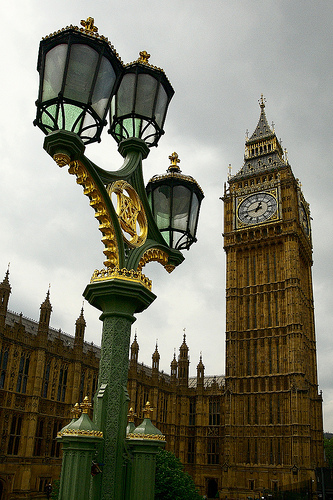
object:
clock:
[234, 189, 279, 229]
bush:
[153, 444, 200, 500]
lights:
[141, 151, 206, 257]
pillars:
[125, 432, 166, 500]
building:
[217, 95, 323, 499]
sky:
[0, 0, 332, 435]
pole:
[91, 301, 136, 499]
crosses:
[76, 394, 91, 414]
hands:
[253, 200, 262, 215]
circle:
[106, 179, 148, 250]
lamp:
[32, 16, 126, 148]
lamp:
[106, 51, 173, 149]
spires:
[0, 260, 12, 298]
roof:
[0, 311, 179, 395]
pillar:
[81, 276, 157, 499]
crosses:
[268, 121, 275, 129]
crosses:
[138, 50, 150, 64]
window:
[15, 417, 24, 437]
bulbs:
[115, 113, 154, 148]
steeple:
[74, 300, 87, 331]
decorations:
[53, 146, 185, 287]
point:
[79, 303, 84, 319]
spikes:
[13, 311, 28, 333]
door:
[201, 473, 220, 499]